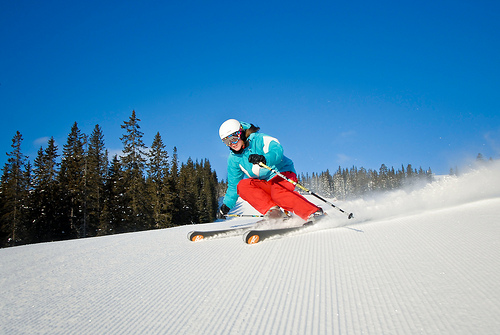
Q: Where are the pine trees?
A: In the back.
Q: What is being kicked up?
A: Snow.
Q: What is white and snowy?
A: Slope.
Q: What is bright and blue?
A: Sky.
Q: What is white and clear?
A: Snow.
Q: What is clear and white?
A: Snow.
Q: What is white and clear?
A: Snow.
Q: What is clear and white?
A: Snow.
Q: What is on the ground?
A: Snow.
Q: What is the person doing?
A: Skiing.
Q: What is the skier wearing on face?
A: Goggles.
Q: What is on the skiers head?
A: Helmet.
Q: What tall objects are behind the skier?
A: Trees.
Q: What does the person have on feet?
A: Skis.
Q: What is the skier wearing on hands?
A: Gloves.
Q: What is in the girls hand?
A: Ski pole.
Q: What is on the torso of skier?
A: Coat.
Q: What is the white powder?
A: Snow.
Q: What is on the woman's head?
A: Helmet.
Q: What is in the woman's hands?
A: Poles.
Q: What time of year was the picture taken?
A: Winter.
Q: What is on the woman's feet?
A: Skis.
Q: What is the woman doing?
A: Skiing.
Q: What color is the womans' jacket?
A: Blue and white.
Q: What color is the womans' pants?
A: Red.